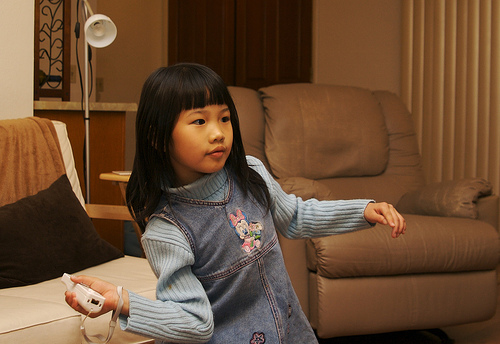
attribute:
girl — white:
[110, 71, 395, 307]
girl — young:
[117, 63, 314, 268]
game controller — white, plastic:
[55, 269, 109, 316]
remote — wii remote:
[52, 272, 114, 322]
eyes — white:
[185, 101, 245, 133]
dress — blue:
[74, 169, 373, 339]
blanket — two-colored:
[0, 115, 127, 292]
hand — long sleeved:
[66, 276, 118, 320]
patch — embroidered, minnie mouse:
[213, 190, 283, 267]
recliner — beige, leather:
[268, 81, 498, 328]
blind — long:
[400, 5, 498, 187]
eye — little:
[189, 116, 206, 126]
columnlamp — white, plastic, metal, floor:
[71, 0, 117, 207]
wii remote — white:
[54, 267, 111, 316]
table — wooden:
[97, 167, 132, 199]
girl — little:
[64, 59, 407, 340]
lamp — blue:
[58, 13, 192, 194]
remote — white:
[48, 263, 108, 318]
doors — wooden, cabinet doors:
[181, 8, 346, 93]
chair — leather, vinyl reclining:
[267, 88, 498, 316]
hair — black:
[126, 61, 273, 231]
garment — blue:
[122, 152, 377, 342]